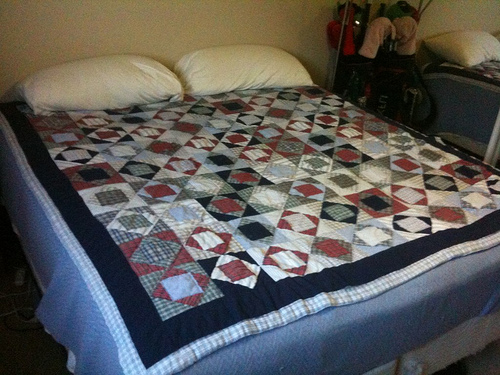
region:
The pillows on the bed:
[9, 29, 315, 116]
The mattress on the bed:
[148, 233, 487, 370]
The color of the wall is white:
[23, 0, 316, 44]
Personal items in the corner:
[327, 0, 443, 130]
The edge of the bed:
[0, 97, 167, 370]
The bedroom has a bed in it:
[23, 15, 496, 365]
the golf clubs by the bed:
[322, 2, 424, 111]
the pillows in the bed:
[17, 33, 307, 110]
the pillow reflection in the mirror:
[425, 21, 499, 67]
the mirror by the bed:
[428, 0, 496, 160]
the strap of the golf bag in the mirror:
[405, 61, 441, 139]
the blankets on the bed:
[1, 107, 498, 373]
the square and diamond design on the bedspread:
[131, 103, 342, 318]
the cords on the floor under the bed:
[0, 238, 43, 338]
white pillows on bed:
[50, 41, 297, 154]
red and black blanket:
[75, 72, 431, 314]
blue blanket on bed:
[304, 302, 439, 374]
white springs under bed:
[441, 324, 488, 369]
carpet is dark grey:
[3, 276, 43, 373]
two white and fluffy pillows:
[37, 32, 322, 135]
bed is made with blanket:
[3, 74, 495, 283]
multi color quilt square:
[139, 260, 220, 324]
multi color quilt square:
[196, 250, 272, 295]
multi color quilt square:
[246, 239, 326, 277]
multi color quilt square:
[292, 230, 361, 269]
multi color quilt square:
[337, 218, 410, 256]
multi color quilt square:
[378, 205, 455, 245]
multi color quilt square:
[118, 227, 191, 273]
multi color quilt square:
[172, 217, 240, 263]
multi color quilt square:
[224, 213, 287, 252]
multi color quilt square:
[262, 205, 332, 237]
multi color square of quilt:
[62, 159, 126, 182]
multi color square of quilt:
[81, 181, 142, 209]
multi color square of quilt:
[98, 204, 170, 241]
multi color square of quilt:
[124, 228, 187, 273]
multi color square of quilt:
[174, 225, 240, 252]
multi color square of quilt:
[131, 174, 186, 206]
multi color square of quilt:
[111, 155, 165, 183]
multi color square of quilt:
[98, 139, 144, 163]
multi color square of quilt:
[49, 147, 106, 166]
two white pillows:
[19, 45, 314, 111]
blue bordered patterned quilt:
[3, 102, 499, 374]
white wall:
[0, 1, 334, 86]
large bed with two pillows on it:
[0, 41, 496, 372]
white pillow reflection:
[425, 29, 496, 69]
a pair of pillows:
[16, 36, 317, 131]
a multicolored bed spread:
[14, 77, 486, 354]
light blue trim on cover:
[0, 162, 110, 364]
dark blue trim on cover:
[10, 126, 152, 324]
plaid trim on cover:
[74, 259, 113, 306]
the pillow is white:
[15, 36, 182, 128]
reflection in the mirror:
[329, 8, 499, 156]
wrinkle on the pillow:
[131, 58, 184, 109]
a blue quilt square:
[163, 263, 205, 305]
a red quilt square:
[214, 248, 266, 310]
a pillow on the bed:
[171, 8, 295, 100]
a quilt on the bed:
[88, 71, 467, 372]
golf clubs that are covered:
[356, 11, 398, 67]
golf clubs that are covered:
[383, 15, 423, 65]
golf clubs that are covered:
[308, 17, 374, 85]